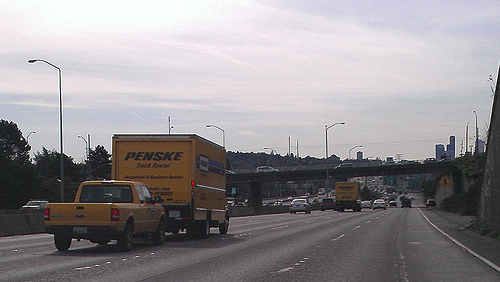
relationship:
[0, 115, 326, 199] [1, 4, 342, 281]
trees on left side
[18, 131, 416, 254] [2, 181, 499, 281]
vehicles on road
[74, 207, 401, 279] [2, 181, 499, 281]
lines on ground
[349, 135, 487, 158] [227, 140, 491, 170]
buildings in distance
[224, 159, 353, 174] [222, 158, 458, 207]
cars on interstate bridge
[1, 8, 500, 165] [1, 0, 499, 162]
sky has clouds